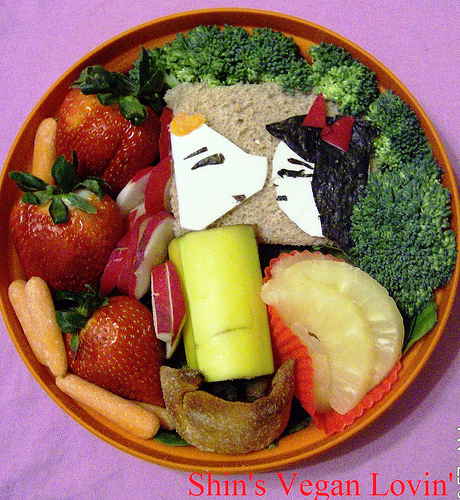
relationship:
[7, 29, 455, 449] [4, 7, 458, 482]
food in a bowl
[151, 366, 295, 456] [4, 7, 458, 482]
fuit in a bowl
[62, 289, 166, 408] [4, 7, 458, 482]
fuit in a bowl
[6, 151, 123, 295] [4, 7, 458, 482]
component in a bowl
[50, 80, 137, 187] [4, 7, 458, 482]
fuit in a bowl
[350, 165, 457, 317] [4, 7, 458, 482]
broccoli in a bowl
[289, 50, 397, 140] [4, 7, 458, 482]
vegetable in a bowl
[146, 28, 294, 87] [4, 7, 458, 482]
vegetable in a bowl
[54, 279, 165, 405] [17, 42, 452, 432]
fruit in bowl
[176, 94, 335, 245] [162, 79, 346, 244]
one slice of bread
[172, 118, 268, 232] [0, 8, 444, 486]
face on plate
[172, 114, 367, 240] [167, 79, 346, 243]
paper on bread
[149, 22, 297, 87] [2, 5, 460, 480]
vegetable on bow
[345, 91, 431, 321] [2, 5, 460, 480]
broccoli on side of bow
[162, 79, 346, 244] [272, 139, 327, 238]
bread has face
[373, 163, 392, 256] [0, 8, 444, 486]
broccoli in plate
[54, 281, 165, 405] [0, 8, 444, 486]
fruit in plate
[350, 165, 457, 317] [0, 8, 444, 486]
broccoli in plate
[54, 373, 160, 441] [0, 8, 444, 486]
carrots in plate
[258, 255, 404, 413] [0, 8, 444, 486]
fruit in plate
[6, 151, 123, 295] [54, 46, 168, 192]
component next fuit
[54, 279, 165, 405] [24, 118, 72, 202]
fruit next carrots